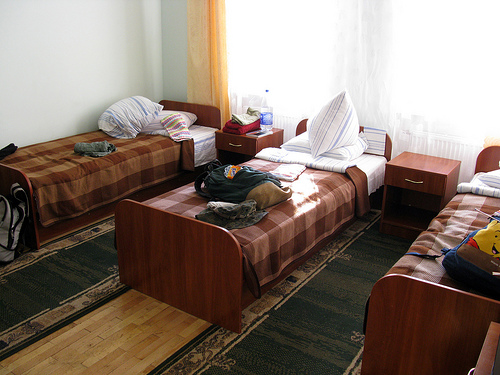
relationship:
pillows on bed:
[285, 104, 375, 182] [243, 189, 360, 264]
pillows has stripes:
[285, 104, 375, 182] [315, 114, 339, 159]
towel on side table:
[226, 120, 260, 135] [214, 128, 256, 171]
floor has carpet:
[77, 306, 164, 352] [10, 249, 99, 323]